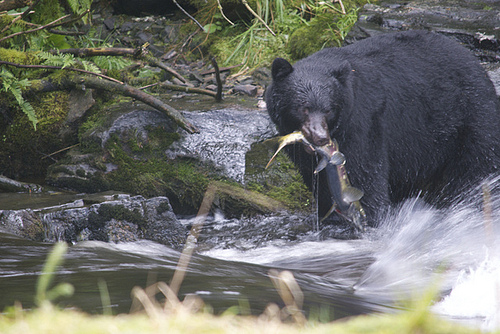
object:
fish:
[260, 128, 370, 233]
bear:
[263, 30, 497, 237]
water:
[0, 224, 496, 289]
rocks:
[89, 193, 188, 244]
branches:
[3, 67, 204, 135]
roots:
[0, 34, 68, 127]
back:
[8, 1, 190, 70]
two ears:
[269, 57, 295, 81]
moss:
[118, 160, 204, 191]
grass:
[39, 90, 67, 123]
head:
[262, 57, 360, 146]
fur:
[364, 49, 450, 170]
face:
[260, 53, 357, 145]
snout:
[297, 109, 333, 146]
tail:
[258, 128, 303, 171]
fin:
[312, 156, 333, 174]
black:
[261, 29, 498, 230]